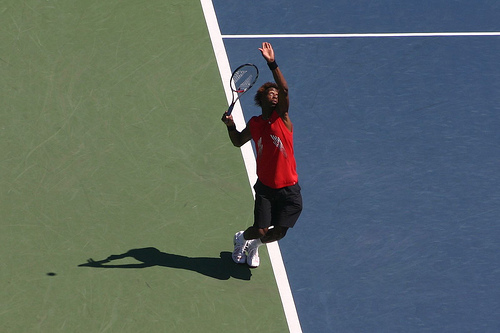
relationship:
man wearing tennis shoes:
[219, 41, 302, 268] [247, 239, 260, 267]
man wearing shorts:
[198, 32, 320, 274] [242, 172, 310, 234]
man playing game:
[219, 41, 302, 268] [64, 60, 409, 279]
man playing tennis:
[219, 41, 302, 268] [124, 58, 483, 300]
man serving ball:
[219, 41, 302, 268] [38, 268, 108, 293]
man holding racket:
[219, 41, 302, 268] [207, 58, 253, 135]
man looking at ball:
[219, 41, 302, 268] [44, 256, 93, 290]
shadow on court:
[80, 245, 251, 284] [7, 4, 498, 329]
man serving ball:
[219, 41, 302, 268] [45, 257, 65, 287]